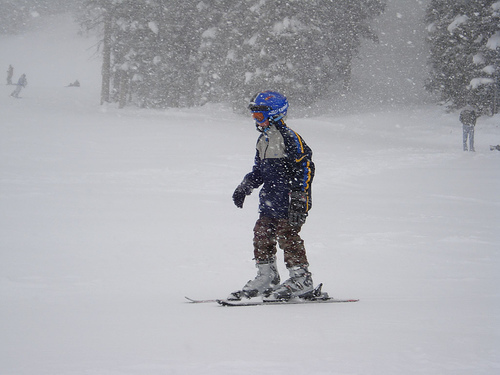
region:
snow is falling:
[3, 5, 499, 361]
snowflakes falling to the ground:
[121, 11, 350, 94]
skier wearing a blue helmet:
[223, 78, 331, 310]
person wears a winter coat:
[219, 84, 339, 312]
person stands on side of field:
[454, 94, 482, 159]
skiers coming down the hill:
[3, 50, 45, 110]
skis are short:
[174, 285, 368, 312]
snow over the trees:
[102, 5, 499, 96]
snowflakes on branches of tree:
[444, 9, 499, 89]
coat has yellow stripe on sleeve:
[226, 120, 321, 220]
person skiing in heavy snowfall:
[48, 15, 371, 348]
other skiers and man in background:
[2, 40, 482, 185]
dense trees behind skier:
[90, 5, 375, 305]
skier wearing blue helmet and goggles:
[245, 85, 286, 130]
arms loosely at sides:
[231, 121, 316, 226]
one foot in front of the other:
[177, 260, 359, 325]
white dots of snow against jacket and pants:
[227, 120, 337, 271]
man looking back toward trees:
[432, 20, 487, 155]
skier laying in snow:
[60, 66, 80, 91]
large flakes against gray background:
[371, 7, 426, 97]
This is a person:
[207, 83, 351, 328]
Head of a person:
[240, 82, 292, 131]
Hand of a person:
[280, 132, 320, 234]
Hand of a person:
[226, 140, 261, 215]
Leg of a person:
[269, 205, 314, 312]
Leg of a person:
[242, 209, 281, 325]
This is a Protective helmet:
[240, 80, 290, 126]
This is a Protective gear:
[230, 80, 317, 301]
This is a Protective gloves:
[285, 202, 308, 228]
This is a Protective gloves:
[230, 184, 249, 213]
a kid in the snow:
[186, 87, 348, 306]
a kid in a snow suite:
[186, 88, 362, 308]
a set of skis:
[186, 285, 360, 308]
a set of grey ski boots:
[227, 262, 322, 301]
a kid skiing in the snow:
[186, 90, 361, 308]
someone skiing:
[7, 70, 34, 102]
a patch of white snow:
[11, 123, 190, 283]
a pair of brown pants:
[249, 208, 313, 275]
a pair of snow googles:
[248, 96, 284, 123]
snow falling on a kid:
[1, 12, 486, 267]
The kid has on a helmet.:
[230, 76, 297, 131]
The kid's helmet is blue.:
[246, 89, 299, 125]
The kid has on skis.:
[201, 267, 398, 317]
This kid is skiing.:
[172, 67, 370, 339]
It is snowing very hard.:
[88, 22, 433, 326]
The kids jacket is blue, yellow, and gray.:
[248, 122, 329, 221]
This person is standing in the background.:
[433, 85, 482, 157]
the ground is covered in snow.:
[18, 151, 200, 348]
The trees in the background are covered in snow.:
[120, 8, 330, 84]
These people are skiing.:
[7, 56, 50, 117]